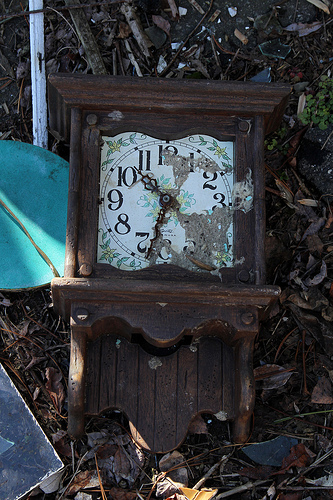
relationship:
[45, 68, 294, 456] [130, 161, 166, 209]
clock has arms of a clock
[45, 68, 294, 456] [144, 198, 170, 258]
clock has clock hands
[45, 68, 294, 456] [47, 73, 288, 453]
clock has brown shelf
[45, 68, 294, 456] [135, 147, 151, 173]
clock has number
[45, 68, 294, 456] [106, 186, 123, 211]
clock has number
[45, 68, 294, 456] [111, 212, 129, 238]
clock has number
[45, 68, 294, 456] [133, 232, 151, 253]
clock has number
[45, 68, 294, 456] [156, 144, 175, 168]
clock has number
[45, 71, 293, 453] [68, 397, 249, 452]
clock stand has design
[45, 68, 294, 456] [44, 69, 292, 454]
clock has clock frame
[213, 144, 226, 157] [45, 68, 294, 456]
flower on corner of clock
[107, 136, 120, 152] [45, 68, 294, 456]
flower on corner of clock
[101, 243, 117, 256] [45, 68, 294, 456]
flower on corner of clock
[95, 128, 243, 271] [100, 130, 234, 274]
web-like material covering clock face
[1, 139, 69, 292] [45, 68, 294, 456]
blue object hiding behind clock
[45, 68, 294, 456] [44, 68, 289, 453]
clock in case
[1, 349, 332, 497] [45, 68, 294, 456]
leaves surrounding clock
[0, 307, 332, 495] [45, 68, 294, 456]
twigs surrounding clock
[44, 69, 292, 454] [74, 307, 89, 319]
clock frame has peg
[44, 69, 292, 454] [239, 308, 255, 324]
clock frame has peg